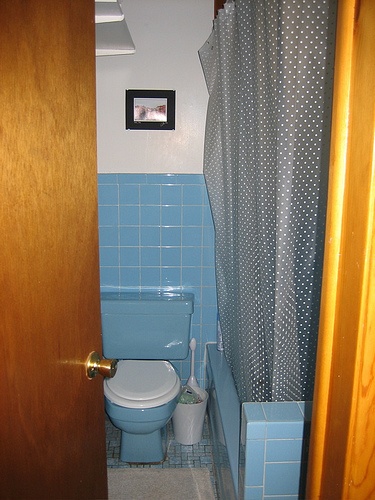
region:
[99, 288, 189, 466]
sparkling clean blue toilet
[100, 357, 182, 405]
closed white toilet seat and top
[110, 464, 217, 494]
white bath mat on floor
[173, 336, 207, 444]
bathroom cleaning tools in container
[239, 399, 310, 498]
blue tile wall of bathtub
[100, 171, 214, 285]
blue ceramic tile wall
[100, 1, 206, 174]
white painted wall above tile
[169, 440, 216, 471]
blue ceramic tile floor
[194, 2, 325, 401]
gray shower curtain with white polka dots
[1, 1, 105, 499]
open door to bathroom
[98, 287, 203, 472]
blue and white toilet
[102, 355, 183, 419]
white toilet seat and cover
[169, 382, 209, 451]
white trach can on floor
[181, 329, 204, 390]
toilet brush against wall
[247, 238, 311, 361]
shower curtain with white polka dots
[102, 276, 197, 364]
blue toilet tank against wall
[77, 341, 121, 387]
gold knob on wood door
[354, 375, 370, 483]
wood grain in door frame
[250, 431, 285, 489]
white grout in blue tile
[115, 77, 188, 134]
picture in black frame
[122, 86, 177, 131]
framed picture on wall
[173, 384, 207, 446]
full white trash can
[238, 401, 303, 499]
light blue tiles on tub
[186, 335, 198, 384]
handle of toilet brush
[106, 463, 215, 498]
cream-colored bath rug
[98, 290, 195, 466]
light blue and white toilet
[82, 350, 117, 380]
brass handle on door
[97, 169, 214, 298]
light blue backsplash tiles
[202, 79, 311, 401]
grey shower curtain with white polka dots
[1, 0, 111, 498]
wooden door with brass handle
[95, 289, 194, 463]
the blue and white toilet by the wall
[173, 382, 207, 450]
the trash can sitting on the floor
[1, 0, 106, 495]
the door to the bathroom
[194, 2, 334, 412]
the polka dot shower curtain hanging from a pole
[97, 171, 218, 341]
the blue tile wall next to the toilet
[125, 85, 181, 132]
the little picture on the wall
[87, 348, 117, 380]
the knob on the door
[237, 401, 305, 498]
the wall at the end of the shower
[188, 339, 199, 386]
the handle of the toilet brush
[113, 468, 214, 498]
the rug on the floor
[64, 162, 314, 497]
Blue tile in the bathroom.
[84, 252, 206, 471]
One toilet in the bathroom.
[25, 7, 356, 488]
Photo is of a bathroom.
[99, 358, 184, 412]
Blue toilet has white seat.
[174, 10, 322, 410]
Shower curtain is clear with dots.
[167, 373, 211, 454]
White trash can beside toilet.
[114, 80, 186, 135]
Painting hanging above the toilet.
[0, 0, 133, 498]
The door is open.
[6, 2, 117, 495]
Door made of wood.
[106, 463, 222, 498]
White bathmat on floor.